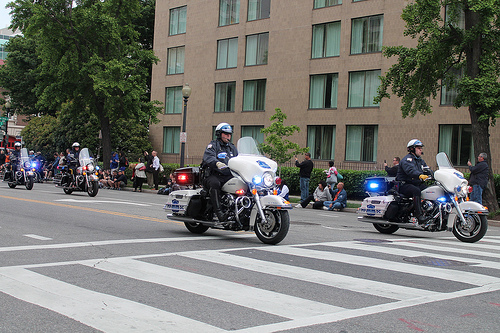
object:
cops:
[391, 138, 432, 225]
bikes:
[356, 151, 490, 243]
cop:
[197, 122, 239, 222]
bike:
[162, 136, 293, 245]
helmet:
[214, 122, 232, 136]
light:
[366, 178, 387, 193]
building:
[147, 0, 499, 201]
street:
[1, 175, 500, 330]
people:
[324, 181, 348, 212]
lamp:
[179, 83, 191, 168]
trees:
[369, 0, 499, 221]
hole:
[403, 255, 480, 267]